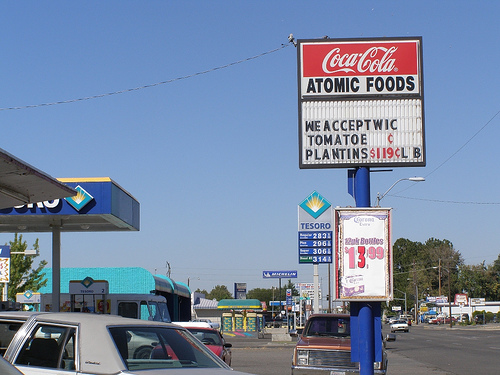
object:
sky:
[0, 3, 500, 312]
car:
[0, 312, 252, 375]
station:
[6, 150, 395, 375]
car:
[390, 319, 410, 333]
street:
[199, 295, 491, 374]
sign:
[296, 40, 421, 167]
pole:
[350, 167, 377, 374]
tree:
[455, 260, 497, 303]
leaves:
[396, 239, 407, 246]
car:
[289, 312, 389, 374]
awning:
[2, 176, 144, 234]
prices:
[298, 231, 333, 263]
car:
[143, 326, 235, 371]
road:
[210, 306, 500, 374]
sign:
[263, 271, 297, 279]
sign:
[298, 192, 333, 264]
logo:
[318, 44, 399, 75]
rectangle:
[302, 43, 417, 76]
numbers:
[312, 256, 318, 263]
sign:
[336, 207, 389, 300]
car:
[0, 315, 161, 359]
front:
[303, 315, 371, 375]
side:
[75, 268, 148, 292]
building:
[26, 263, 194, 323]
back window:
[107, 324, 223, 368]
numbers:
[376, 147, 380, 159]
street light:
[406, 176, 427, 183]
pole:
[379, 178, 407, 200]